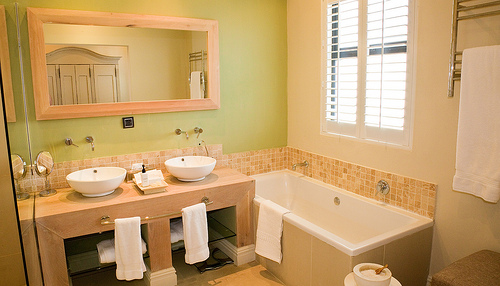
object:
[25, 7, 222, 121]
mirror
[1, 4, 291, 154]
wall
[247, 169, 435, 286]
bathtub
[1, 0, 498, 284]
bathroom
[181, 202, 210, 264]
towel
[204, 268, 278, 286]
ground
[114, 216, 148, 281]
tangle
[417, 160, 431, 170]
ground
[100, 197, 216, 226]
rack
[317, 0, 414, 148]
blinds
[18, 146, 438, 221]
tile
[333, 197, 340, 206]
drain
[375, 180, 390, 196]
knob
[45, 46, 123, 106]
door reflection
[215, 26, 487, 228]
wall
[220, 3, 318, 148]
wall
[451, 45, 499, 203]
towel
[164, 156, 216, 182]
sink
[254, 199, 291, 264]
towel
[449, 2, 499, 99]
towel rack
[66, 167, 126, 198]
basin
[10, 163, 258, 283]
counter